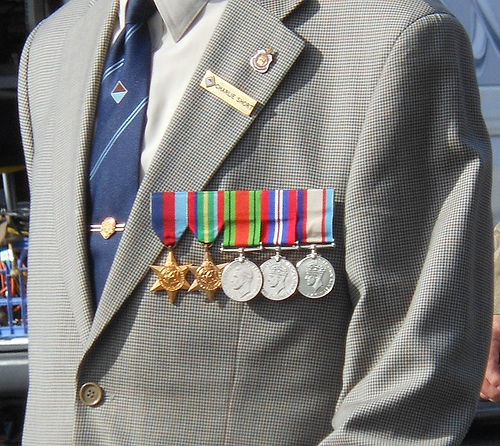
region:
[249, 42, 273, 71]
pendant on suit lapel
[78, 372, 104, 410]
button on the jacket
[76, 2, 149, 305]
blue tie on man's neck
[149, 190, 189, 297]
gold star ribbon on jacket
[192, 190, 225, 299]
ribbon with golden star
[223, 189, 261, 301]
silver pendant on ribbon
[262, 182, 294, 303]
red and blue ribbon attached to silver pendant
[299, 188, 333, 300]
silver pendant attached to ribbon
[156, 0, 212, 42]
collar on the white shirt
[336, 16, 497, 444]
sleeve on the man's jacket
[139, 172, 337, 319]
Service medal on a suit jacket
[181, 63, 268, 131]
Name tag on a suit jacket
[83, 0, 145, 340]
Man wearing a blue tie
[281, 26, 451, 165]
man wearing a plaid jacket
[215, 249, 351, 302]
coins on a medal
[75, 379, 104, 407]
button on a jacket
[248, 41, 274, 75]
button on a jacket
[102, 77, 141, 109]
diamond on a blue tie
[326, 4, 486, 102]
man with broad shoulders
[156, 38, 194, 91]
Man with a white dress shirt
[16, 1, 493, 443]
the mans suit jacket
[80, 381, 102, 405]
the button on the jacket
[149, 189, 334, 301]
the row of medals on the jacket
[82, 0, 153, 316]
the blue tie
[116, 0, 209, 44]
the collar on the white shirt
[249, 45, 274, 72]
the pin on the lapel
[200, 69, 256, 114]
the name tag on the lapel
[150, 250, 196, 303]
the star medal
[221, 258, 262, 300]
the coin medal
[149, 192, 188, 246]
the ribbon attached to the gold star